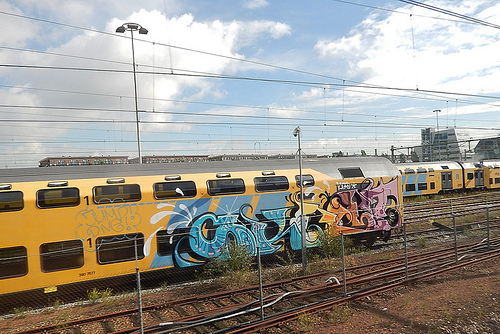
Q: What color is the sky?
A: Blue.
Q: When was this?
A: Daytime.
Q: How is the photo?
A: Clear.